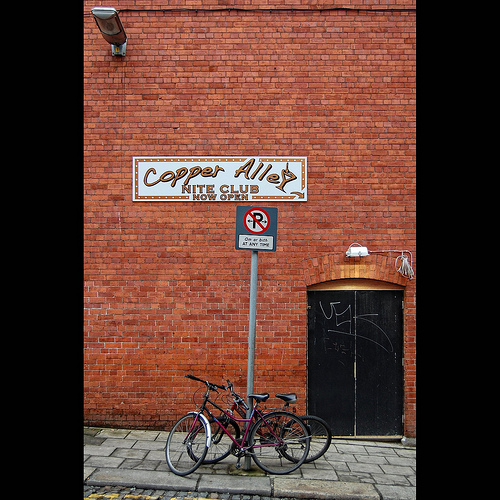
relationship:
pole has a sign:
[243, 248, 259, 470] [231, 199, 281, 251]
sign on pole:
[231, 199, 281, 251] [243, 248, 259, 470]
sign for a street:
[231, 199, 281, 251] [85, 485, 417, 499]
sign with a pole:
[231, 199, 281, 251] [243, 248, 259, 470]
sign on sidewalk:
[231, 199, 281, 251] [84, 425, 416, 500]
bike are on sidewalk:
[165, 374, 313, 477] [84, 425, 416, 500]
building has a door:
[85, 0, 416, 447] [306, 277, 404, 443]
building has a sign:
[85, 0, 416, 447] [133, 157, 307, 202]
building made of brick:
[85, 0, 416, 447] [208, 330, 222, 337]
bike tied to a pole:
[165, 374, 313, 477] [243, 248, 259, 470]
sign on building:
[133, 157, 307, 202] [85, 0, 416, 447]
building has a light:
[85, 0, 416, 447] [91, 6, 129, 57]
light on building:
[347, 247, 370, 257] [85, 0, 416, 447]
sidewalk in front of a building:
[84, 425, 416, 500] [85, 0, 416, 447]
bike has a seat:
[165, 374, 311, 477] [247, 393, 270, 402]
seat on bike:
[276, 392, 298, 402] [187, 379, 332, 465]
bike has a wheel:
[165, 374, 311, 477] [165, 408, 212, 475]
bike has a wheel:
[165, 374, 311, 477] [249, 411, 311, 475]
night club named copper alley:
[85, 0, 416, 447] [133, 157, 307, 202]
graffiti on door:
[317, 299, 395, 355] [306, 277, 404, 443]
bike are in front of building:
[165, 374, 313, 477] [85, 0, 416, 447]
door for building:
[306, 277, 404, 443] [85, 0, 416, 447]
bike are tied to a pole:
[165, 374, 313, 477] [243, 248, 259, 470]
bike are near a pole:
[165, 374, 313, 477] [243, 248, 259, 470]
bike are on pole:
[165, 374, 313, 477] [243, 248, 259, 470]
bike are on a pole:
[165, 374, 313, 477] [243, 248, 259, 470]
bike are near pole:
[165, 374, 313, 477] [243, 248, 259, 470]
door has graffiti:
[306, 277, 404, 443] [317, 299, 395, 355]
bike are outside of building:
[165, 374, 313, 477] [85, 0, 416, 447]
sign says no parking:
[231, 199, 281, 251] [242, 236, 271, 248]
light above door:
[347, 247, 370, 257] [306, 277, 404, 443]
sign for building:
[133, 157, 307, 202] [85, 0, 416, 447]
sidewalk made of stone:
[84, 425, 416, 500] [130, 486, 142, 494]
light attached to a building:
[91, 6, 129, 57] [85, 0, 416, 447]